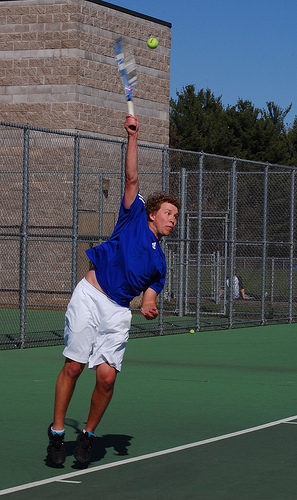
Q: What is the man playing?
A: Tennis.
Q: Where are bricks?
A: On building structure.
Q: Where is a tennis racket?
A: In man's hand.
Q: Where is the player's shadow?
A: On the court.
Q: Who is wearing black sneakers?
A: Man playing tennis.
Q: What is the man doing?
A: Playing tennis.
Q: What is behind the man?
A: A chain link fence.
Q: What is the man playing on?
A: A green court.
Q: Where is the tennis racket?
A: In the man's right hand.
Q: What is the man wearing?
A: A blue shirt and white shorts.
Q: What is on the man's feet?
A: Black shoes.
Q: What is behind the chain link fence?
A: A brick building.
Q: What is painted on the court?
A: A white line.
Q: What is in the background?
A: Trees.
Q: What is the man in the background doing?
A: Sitting down.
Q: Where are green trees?
A: Behind a tennis court.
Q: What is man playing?
A: Tennis.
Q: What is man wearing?
A: Blue shirt.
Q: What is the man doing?
A: About to hit a ball with a tennis racket.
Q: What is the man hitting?
A: A tennis ball.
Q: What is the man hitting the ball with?
A: A tennis racket.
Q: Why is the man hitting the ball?
A: He is playing tennis.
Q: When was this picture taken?
A: During the day.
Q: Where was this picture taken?
A: A tennis court.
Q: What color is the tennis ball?
A: Yellow.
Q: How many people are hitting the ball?
A: One.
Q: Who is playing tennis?
A: The man with the blue shirt.